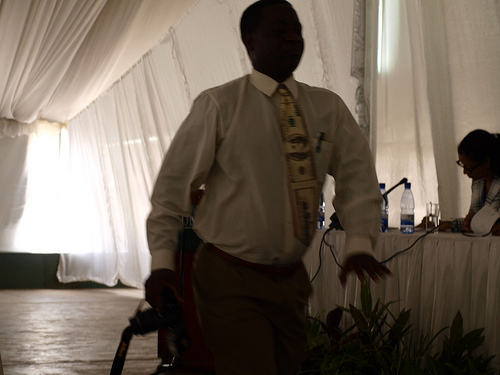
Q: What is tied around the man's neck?
A: Tie.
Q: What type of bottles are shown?
A: Water bottles.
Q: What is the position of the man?
A: Standing.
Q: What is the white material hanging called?
A: Curtains.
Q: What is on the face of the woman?
A: Glasses.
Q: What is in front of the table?
A: Plants.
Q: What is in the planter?
A: Plants.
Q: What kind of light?
A: Sunlight.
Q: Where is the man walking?
A: Room.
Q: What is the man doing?
A: Dancing.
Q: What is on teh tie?
A: Money.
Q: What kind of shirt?
A: Long sleeve.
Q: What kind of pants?
A: Tan.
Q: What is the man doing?
A: Standing.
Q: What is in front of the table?
A: Plants.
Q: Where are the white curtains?
A: Behind the man.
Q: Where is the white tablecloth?
A: On the table.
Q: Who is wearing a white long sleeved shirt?
A: The man.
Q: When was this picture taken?
A: Daytime.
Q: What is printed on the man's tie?
A: A $100 Bill.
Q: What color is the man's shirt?
A: White.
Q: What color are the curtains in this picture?
A: White.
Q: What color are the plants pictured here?
A: Green.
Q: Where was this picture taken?
A: In a Tent.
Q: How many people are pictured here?
A: Two.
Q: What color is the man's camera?
A: Black.